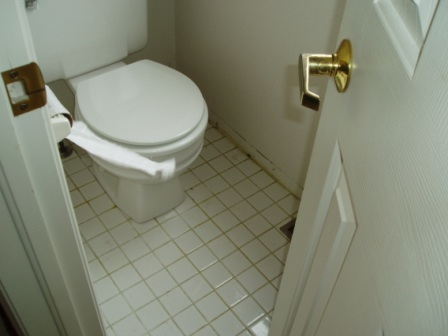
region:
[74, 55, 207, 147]
A white wooden toilet seat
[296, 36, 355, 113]
A brass door handle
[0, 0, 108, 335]
A white wooden door frame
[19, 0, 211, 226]
A white porcelin toilet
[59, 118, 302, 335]
A dirty tile floor in a bathroom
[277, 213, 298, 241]
A floor vent in a bathroom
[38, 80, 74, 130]
An almost empty roll of toilet paper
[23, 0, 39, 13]
A silver toilet flush lever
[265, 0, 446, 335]
A wooden bathroom door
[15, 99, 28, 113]
A brass screw on a door frame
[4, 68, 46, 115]
door stopper on the wall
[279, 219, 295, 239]
heater on the floor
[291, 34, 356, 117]
gold handle on the door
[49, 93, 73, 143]
toliet paper roll holder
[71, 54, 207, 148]
cover of the toilet seat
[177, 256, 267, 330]
shiny white tiled floor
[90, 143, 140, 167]
toliet paper on the toliet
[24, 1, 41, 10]
handle to flush the toliet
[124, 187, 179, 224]
base of the toliet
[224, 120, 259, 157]
white baseboard on the floor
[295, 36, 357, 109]
A gold door knob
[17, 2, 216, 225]
A toilet in the bathroom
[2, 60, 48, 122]
The latch in the door frame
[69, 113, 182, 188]
Some toilet paper floating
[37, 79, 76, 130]
An empty roll of toilet paper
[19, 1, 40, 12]
The lever on the toilet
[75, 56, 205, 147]
The lid of the toilet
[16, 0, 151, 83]
The toilet tank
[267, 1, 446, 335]
The bathroom door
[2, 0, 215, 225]
A white commode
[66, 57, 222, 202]
the toilet cover is closed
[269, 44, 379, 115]
door handle is gold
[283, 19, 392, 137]
door handle is gold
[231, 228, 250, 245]
white tile on floor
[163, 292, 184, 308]
white tile on floor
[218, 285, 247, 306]
white tile on floor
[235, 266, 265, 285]
white tile on floor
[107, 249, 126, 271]
white tile on floor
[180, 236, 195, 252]
white tile on floor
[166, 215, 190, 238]
white tile on floor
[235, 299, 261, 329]
white tile on floor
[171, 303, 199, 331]
white tile on floor